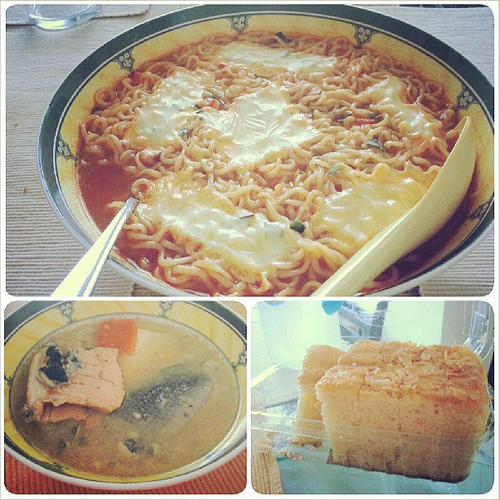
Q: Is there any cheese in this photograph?
A: Yes, there is cheese.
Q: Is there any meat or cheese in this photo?
A: Yes, there is cheese.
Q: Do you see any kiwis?
A: No, there are no kiwis.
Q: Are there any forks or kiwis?
A: No, there are no kiwis or forks.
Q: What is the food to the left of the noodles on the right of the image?
A: The food is cheese.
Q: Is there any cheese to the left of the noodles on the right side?
A: Yes, there is cheese to the left of the noodles.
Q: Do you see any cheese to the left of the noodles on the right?
A: Yes, there is cheese to the left of the noodles.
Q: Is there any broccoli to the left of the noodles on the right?
A: No, there is cheese to the left of the noodles.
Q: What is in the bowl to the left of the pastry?
A: The fish is in the bowl.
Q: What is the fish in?
A: The fish is in the bowl.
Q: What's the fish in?
A: The fish is in the bowl.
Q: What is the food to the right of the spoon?
A: The food is noodles.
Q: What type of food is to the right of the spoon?
A: The food is noodles.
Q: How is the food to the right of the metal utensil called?
A: The food is noodles.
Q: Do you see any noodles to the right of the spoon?
A: Yes, there are noodles to the right of the spoon.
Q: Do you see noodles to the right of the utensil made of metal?
A: Yes, there are noodles to the right of the spoon.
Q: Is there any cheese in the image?
A: Yes, there is cheese.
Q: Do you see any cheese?
A: Yes, there is cheese.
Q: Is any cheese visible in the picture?
A: Yes, there is cheese.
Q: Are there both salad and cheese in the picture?
A: No, there is cheese but no salad.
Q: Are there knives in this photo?
A: No, there are no knives.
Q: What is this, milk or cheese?
A: This is cheese.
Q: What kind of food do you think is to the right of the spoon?
A: The food is cheese.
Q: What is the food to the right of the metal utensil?
A: The food is cheese.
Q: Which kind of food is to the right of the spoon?
A: The food is cheese.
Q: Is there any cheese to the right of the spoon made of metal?
A: Yes, there is cheese to the right of the spoon.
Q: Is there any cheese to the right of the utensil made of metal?
A: Yes, there is cheese to the right of the spoon.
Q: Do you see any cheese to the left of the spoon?
A: No, the cheese is to the right of the spoon.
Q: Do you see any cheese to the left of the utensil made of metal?
A: No, the cheese is to the right of the spoon.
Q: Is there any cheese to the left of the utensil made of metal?
A: No, the cheese is to the right of the spoon.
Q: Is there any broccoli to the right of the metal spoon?
A: No, there is cheese to the right of the spoon.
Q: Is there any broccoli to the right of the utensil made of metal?
A: No, there is cheese to the right of the spoon.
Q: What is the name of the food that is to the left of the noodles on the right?
A: The food is cheese.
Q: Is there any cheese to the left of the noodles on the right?
A: Yes, there is cheese to the left of the noodles.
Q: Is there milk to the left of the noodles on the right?
A: No, there is cheese to the left of the noodles.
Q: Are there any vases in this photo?
A: No, there are no vases.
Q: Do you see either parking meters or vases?
A: No, there are no vases or parking meters.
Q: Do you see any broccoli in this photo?
A: No, there is no broccoli.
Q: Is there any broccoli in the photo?
A: No, there is no broccoli.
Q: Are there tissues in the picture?
A: No, there are no tissues.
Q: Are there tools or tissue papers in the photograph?
A: No, there are no tissue papers or tools.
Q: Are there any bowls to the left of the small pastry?
A: Yes, there is a bowl to the left of the pastry.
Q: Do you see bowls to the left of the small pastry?
A: Yes, there is a bowl to the left of the pastry.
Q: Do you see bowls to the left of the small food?
A: Yes, there is a bowl to the left of the pastry.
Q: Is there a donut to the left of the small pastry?
A: No, there is a bowl to the left of the pastry.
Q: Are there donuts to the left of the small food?
A: No, there is a bowl to the left of the pastry.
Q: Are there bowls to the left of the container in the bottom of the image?
A: Yes, there is a bowl to the left of the container.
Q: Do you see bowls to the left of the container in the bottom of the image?
A: Yes, there is a bowl to the left of the container.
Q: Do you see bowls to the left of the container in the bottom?
A: Yes, there is a bowl to the left of the container.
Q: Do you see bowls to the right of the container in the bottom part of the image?
A: No, the bowl is to the left of the container.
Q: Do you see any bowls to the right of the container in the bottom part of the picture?
A: No, the bowl is to the left of the container.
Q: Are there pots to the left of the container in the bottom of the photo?
A: No, there is a bowl to the left of the container.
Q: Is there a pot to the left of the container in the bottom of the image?
A: No, there is a bowl to the left of the container.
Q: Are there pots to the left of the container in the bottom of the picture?
A: No, there is a bowl to the left of the container.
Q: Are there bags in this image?
A: No, there are no bags.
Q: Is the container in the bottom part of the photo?
A: Yes, the container is in the bottom of the image.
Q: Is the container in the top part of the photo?
A: No, the container is in the bottom of the image.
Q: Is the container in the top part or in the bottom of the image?
A: The container is in the bottom of the image.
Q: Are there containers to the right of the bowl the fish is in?
A: Yes, there is a container to the right of the bowl.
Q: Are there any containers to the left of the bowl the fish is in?
A: No, the container is to the right of the bowl.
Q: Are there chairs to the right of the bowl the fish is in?
A: No, there is a container to the right of the bowl.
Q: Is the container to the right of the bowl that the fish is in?
A: Yes, the container is to the right of the bowl.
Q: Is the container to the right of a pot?
A: No, the container is to the right of the bowl.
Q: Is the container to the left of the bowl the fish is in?
A: No, the container is to the right of the bowl.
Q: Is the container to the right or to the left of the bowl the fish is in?
A: The container is to the right of the bowl.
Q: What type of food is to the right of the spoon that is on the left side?
A: The food is noodles.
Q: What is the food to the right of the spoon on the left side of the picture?
A: The food is noodles.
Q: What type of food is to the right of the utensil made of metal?
A: The food is noodles.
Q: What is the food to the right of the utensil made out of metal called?
A: The food is noodles.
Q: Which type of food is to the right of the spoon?
A: The food is noodles.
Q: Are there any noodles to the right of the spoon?
A: Yes, there are noodles to the right of the spoon.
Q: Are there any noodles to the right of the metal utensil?
A: Yes, there are noodles to the right of the spoon.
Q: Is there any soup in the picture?
A: Yes, there is soup.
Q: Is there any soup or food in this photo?
A: Yes, there is soup.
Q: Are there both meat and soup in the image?
A: Yes, there are both soup and meat.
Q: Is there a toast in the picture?
A: No, there are no toasts.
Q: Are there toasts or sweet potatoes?
A: No, there are no toasts or sweet potatoes.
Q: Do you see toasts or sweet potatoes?
A: No, there are no toasts or sweet potatoes.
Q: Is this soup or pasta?
A: This is soup.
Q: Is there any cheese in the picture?
A: Yes, there is cheese.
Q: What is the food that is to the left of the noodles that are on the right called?
A: The food is cheese.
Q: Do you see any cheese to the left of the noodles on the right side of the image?
A: Yes, there is cheese to the left of the noodles.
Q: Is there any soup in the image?
A: Yes, there is soup.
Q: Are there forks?
A: No, there are no forks.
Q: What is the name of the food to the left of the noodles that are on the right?
A: The food is soup.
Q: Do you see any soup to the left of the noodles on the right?
A: Yes, there is soup to the left of the noodles.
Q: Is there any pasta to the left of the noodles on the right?
A: No, there is soup to the left of the noodles.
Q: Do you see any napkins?
A: No, there are no napkins.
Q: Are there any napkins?
A: No, there are no napkins.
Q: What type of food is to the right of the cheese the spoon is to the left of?
A: The food is noodles.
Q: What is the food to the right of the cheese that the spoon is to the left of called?
A: The food is noodles.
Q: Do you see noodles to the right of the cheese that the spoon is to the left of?
A: Yes, there are noodles to the right of the cheese.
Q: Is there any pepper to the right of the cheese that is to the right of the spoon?
A: No, there are noodles to the right of the cheese.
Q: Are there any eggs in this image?
A: No, there are no eggs.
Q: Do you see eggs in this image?
A: No, there are no eggs.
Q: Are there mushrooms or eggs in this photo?
A: No, there are no eggs or mushrooms.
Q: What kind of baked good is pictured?
A: The baked good is a pastry.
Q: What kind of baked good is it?
A: The food is a pastry.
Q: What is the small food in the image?
A: The food is a pastry.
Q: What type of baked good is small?
A: The baked good is a pastry.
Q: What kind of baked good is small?
A: The baked good is a pastry.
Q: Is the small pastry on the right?
A: Yes, the pastry is on the right of the image.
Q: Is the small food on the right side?
A: Yes, the pastry is on the right of the image.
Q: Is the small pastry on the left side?
A: No, the pastry is on the right of the image.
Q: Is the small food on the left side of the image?
A: No, the pastry is on the right of the image.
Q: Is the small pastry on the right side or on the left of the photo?
A: The pastry is on the right of the image.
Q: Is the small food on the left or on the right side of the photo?
A: The pastry is on the right of the image.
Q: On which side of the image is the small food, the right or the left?
A: The pastry is on the right of the image.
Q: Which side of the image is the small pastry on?
A: The pastry is on the right of the image.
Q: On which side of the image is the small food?
A: The pastry is on the right of the image.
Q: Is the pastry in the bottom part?
A: Yes, the pastry is in the bottom of the image.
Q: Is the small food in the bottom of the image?
A: Yes, the pastry is in the bottom of the image.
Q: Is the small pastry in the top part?
A: No, the pastry is in the bottom of the image.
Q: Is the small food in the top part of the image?
A: No, the pastry is in the bottom of the image.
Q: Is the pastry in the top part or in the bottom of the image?
A: The pastry is in the bottom of the image.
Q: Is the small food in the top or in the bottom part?
A: The pastry is in the bottom of the image.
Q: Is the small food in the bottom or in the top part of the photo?
A: The pastry is in the bottom of the image.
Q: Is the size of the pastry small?
A: Yes, the pastry is small.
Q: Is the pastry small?
A: Yes, the pastry is small.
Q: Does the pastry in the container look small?
A: Yes, the pastry is small.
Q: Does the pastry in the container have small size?
A: Yes, the pastry is small.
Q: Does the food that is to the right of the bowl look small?
A: Yes, the pastry is small.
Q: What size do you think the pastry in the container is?
A: The pastry is small.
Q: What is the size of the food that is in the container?
A: The pastry is small.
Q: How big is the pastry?
A: The pastry is small.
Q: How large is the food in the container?
A: The pastry is small.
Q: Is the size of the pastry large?
A: No, the pastry is small.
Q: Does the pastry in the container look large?
A: No, the pastry is small.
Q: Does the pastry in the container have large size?
A: No, the pastry is small.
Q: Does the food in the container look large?
A: No, the pastry is small.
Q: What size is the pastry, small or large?
A: The pastry is small.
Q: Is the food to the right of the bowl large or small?
A: The pastry is small.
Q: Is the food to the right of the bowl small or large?
A: The pastry is small.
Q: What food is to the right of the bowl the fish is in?
A: The food is a pastry.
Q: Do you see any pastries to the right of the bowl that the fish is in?
A: Yes, there is a pastry to the right of the bowl.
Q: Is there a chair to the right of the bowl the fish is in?
A: No, there is a pastry to the right of the bowl.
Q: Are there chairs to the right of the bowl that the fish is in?
A: No, there is a pastry to the right of the bowl.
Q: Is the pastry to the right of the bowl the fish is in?
A: Yes, the pastry is to the right of the bowl.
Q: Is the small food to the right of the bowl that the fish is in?
A: Yes, the pastry is to the right of the bowl.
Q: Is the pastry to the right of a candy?
A: No, the pastry is to the right of the bowl.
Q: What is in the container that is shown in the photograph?
A: The pastry is in the container.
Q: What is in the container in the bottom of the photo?
A: The pastry is in the container.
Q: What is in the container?
A: The pastry is in the container.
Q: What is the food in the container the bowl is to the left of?
A: The food is a pastry.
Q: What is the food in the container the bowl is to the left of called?
A: The food is a pastry.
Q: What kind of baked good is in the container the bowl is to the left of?
A: The food is a pastry.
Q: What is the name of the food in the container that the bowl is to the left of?
A: The food is a pastry.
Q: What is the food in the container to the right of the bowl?
A: The food is a pastry.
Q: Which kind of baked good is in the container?
A: The food is a pastry.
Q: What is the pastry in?
A: The pastry is in the container.